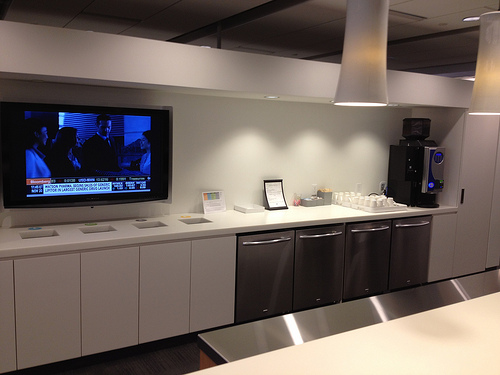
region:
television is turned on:
[10, 111, 190, 203]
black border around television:
[17, 103, 171, 198]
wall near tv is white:
[177, 113, 275, 174]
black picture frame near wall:
[256, 178, 308, 239]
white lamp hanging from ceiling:
[308, 4, 403, 134]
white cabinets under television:
[8, 230, 250, 363]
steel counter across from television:
[222, 268, 495, 369]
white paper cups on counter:
[339, 178, 403, 212]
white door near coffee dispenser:
[455, 124, 497, 289]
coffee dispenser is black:
[370, 125, 472, 223]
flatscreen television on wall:
[4, 83, 193, 213]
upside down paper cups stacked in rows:
[332, 173, 405, 210]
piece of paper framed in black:
[261, 177, 292, 209]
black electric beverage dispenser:
[382, 113, 453, 208]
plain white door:
[454, 109, 494, 274]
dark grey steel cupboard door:
[233, 227, 294, 321]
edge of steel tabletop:
[196, 319, 277, 361]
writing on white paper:
[196, 184, 234, 219]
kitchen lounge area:
[7, 44, 495, 371]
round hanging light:
[323, 36, 396, 123]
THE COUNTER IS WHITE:
[0, 187, 457, 262]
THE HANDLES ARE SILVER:
[229, 217, 437, 252]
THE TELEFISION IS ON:
[0, 102, 180, 214]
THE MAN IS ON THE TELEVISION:
[81, 114, 128, 179]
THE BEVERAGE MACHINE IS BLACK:
[376, 114, 445, 211]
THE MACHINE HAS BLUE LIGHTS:
[421, 145, 446, 195]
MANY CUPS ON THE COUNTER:
[329, 187, 401, 220]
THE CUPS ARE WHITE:
[326, 177, 403, 219]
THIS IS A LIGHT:
[326, 1, 399, 121]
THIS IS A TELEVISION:
[0, 100, 175, 212]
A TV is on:
[1, 105, 172, 203]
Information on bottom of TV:
[27, 178, 152, 197]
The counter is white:
[0, 240, 232, 362]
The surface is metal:
[202, 268, 499, 353]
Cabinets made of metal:
[240, 213, 427, 316]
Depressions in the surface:
[19, 214, 211, 239]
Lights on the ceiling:
[335, 2, 498, 117]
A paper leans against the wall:
[260, 178, 290, 212]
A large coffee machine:
[384, 118, 441, 206]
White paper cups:
[334, 192, 404, 215]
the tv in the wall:
[1, 97, 178, 204]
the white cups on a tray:
[336, 189, 396, 211]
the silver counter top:
[198, 272, 498, 349]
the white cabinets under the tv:
[0, 245, 229, 330]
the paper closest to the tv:
[204, 187, 229, 212]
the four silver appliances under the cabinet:
[227, 215, 430, 305]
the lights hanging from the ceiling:
[328, 0, 498, 125]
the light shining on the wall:
[210, 122, 399, 202]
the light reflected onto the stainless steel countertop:
[280, 313, 312, 346]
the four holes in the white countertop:
[16, 210, 213, 243]